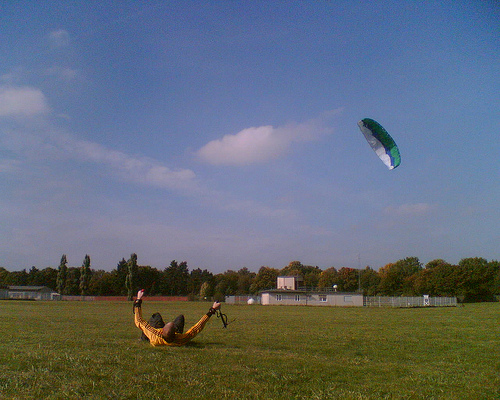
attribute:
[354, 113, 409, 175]
kite — green, white